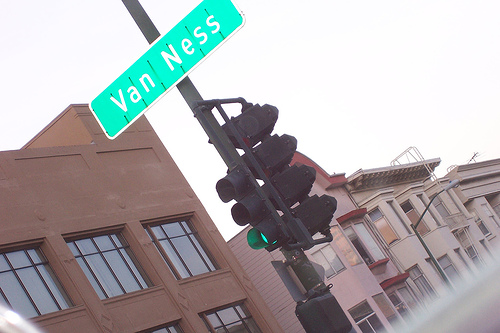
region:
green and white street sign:
[64, 2, 264, 148]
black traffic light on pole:
[181, 85, 376, 330]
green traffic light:
[232, 222, 284, 260]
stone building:
[2, 88, 297, 332]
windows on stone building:
[2, 193, 217, 332]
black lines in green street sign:
[98, 0, 230, 126]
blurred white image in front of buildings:
[390, 250, 499, 331]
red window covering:
[376, 268, 411, 296]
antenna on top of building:
[459, 144, 489, 168]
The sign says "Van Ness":
[44, 14, 280, 131]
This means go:
[236, 207, 299, 267]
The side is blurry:
[358, 245, 499, 331]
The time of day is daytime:
[273, 40, 397, 152]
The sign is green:
[61, 18, 283, 145]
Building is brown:
[18, 145, 164, 214]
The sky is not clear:
[13, 15, 91, 67]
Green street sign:
[83, 0, 250, 153]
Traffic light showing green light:
[203, 95, 337, 269]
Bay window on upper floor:
[338, 203, 391, 279]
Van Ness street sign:
[83, 0, 249, 159]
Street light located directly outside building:
[404, 168, 471, 313]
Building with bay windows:
[363, 153, 493, 325]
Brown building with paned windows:
[3, 196, 228, 321]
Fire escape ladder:
[453, 217, 487, 288]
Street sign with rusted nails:
[88, 0, 249, 155]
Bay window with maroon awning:
[340, 202, 393, 285]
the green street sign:
[88, 0, 245, 140]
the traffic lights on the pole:
[190, 96, 337, 251]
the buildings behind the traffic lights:
[0, 102, 497, 331]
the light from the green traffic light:
[245, 226, 277, 249]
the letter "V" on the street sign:
[109, 88, 127, 112]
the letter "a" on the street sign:
[127, 85, 142, 102]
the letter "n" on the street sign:
[138, 73, 155, 92]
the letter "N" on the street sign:
[160, 43, 182, 70]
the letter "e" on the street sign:
[180, 38, 193, 55]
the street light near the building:
[409, 178, 460, 298]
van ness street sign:
[72, 8, 252, 150]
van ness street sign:
[71, 5, 245, 146]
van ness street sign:
[67, 0, 252, 149]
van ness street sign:
[79, 5, 254, 150]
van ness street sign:
[78, 3, 258, 150]